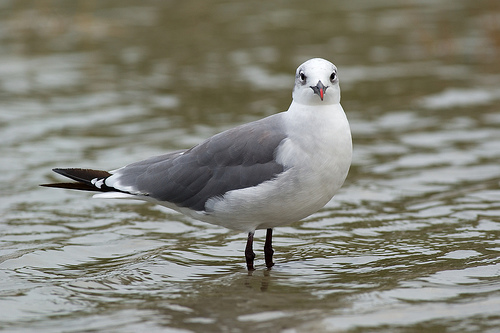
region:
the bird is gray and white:
[42, 27, 389, 304]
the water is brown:
[15, 8, 460, 320]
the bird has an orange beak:
[285, 48, 352, 117]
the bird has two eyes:
[270, 38, 352, 111]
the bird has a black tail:
[37, 144, 149, 220]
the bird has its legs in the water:
[44, 43, 378, 295]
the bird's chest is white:
[270, 52, 363, 219]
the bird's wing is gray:
[125, 111, 296, 215]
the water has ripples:
[43, 93, 451, 318]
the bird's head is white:
[270, 37, 372, 129]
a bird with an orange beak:
[35, 51, 357, 274]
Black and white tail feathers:
[35, 156, 112, 191]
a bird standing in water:
[30, 50, 355, 325]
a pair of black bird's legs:
[226, 225, 277, 276]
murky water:
[311, 225, 467, 325]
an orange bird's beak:
[305, 75, 330, 100]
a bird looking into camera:
[30, 45, 370, 290]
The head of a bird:
[290, 50, 340, 105]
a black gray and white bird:
[35, 51, 356, 267]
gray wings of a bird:
[102, 110, 287, 215]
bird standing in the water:
[26, 17, 458, 293]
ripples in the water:
[351, 225, 481, 322]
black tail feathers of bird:
[40, 149, 127, 206]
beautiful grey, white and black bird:
[33, 55, 360, 275]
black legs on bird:
[223, 217, 299, 285]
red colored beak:
[311, 76, 331, 104]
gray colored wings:
[156, 133, 306, 223]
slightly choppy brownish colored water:
[40, 220, 166, 322]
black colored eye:
[295, 65, 310, 86]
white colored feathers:
[306, 134, 334, 209]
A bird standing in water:
[24, 33, 379, 293]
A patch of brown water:
[333, 234, 478, 304]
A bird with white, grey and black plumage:
[60, 57, 348, 223]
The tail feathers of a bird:
[31, 161, 116, 196]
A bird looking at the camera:
[283, 51, 349, 113]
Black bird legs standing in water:
[243, 219, 284, 288]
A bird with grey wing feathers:
[109, 111, 285, 202]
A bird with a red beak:
[308, 81, 333, 105]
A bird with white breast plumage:
[280, 50, 355, 229]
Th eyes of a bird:
[295, 57, 338, 83]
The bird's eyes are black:
[296, 66, 339, 83]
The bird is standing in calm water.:
[92, 223, 467, 295]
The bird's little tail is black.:
[38, 160, 114, 206]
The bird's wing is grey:
[111, 113, 291, 215]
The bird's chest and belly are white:
[216, 110, 360, 237]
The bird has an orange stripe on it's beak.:
[318, 87, 326, 99]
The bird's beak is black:
[308, 80, 330, 101]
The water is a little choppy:
[12, 13, 495, 331]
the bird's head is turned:
[277, 51, 359, 121]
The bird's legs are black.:
[241, 225, 276, 272]